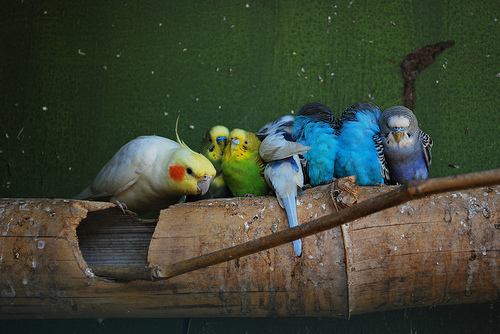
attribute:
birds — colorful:
[74, 86, 446, 266]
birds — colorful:
[70, 95, 455, 257]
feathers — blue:
[262, 117, 296, 257]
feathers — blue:
[304, 107, 332, 185]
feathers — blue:
[339, 100, 383, 189]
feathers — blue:
[389, 101, 431, 187]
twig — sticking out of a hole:
[81, 248, 280, 289]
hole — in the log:
[66, 197, 168, 286]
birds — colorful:
[378, 101, 437, 185]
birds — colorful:
[326, 95, 393, 188]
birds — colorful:
[277, 99, 341, 190]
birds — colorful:
[247, 111, 314, 258]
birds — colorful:
[201, 123, 269, 207]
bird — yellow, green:
[203, 112, 293, 187]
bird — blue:
[238, 100, 323, 206]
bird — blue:
[247, 100, 467, 217]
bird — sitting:
[67, 96, 478, 210]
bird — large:
[52, 117, 225, 220]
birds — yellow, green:
[178, 104, 288, 184]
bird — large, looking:
[108, 126, 222, 212]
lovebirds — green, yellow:
[209, 120, 264, 188]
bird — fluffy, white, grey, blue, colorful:
[380, 100, 434, 188]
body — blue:
[387, 142, 435, 178]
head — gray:
[383, 104, 419, 142]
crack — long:
[130, 181, 420, 281]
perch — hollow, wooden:
[16, 189, 476, 313]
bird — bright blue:
[338, 103, 386, 191]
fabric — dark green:
[10, 11, 463, 184]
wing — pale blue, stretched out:
[259, 134, 310, 164]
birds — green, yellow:
[200, 121, 259, 195]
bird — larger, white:
[86, 130, 220, 201]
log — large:
[13, 184, 460, 300]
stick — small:
[110, 171, 471, 272]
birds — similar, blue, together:
[299, 105, 387, 195]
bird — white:
[90, 124, 222, 206]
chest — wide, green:
[224, 159, 254, 179]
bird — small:
[222, 125, 262, 194]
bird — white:
[96, 133, 236, 201]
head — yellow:
[165, 146, 216, 196]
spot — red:
[168, 162, 183, 178]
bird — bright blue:
[340, 111, 380, 181]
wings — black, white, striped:
[338, 132, 388, 155]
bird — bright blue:
[307, 121, 333, 182]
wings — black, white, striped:
[310, 135, 336, 180]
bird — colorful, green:
[218, 127, 269, 197]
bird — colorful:
[252, 114, 312, 257]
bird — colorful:
[289, 99, 339, 185]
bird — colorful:
[335, 96, 390, 185]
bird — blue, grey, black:
[374, 103, 430, 186]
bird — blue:
[283, 106, 335, 186]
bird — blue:
[335, 104, 389, 184]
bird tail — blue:
[279, 190, 302, 257]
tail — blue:
[279, 192, 304, 261]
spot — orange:
[166, 161, 189, 186]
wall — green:
[3, 1, 495, 201]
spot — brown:
[401, 41, 459, 106]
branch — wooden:
[1, 186, 495, 320]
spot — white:
[30, 231, 50, 260]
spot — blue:
[216, 132, 236, 149]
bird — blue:
[288, 98, 345, 187]